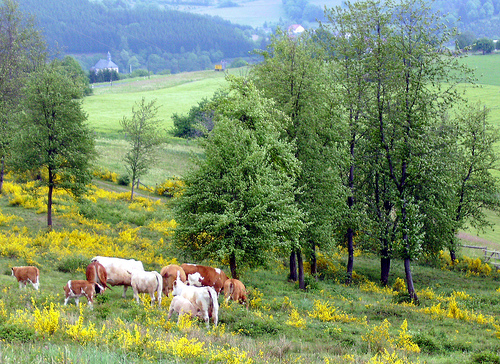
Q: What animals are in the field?
A: Cows.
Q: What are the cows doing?
A: Grazing.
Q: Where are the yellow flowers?
A: In the field.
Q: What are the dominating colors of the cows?
A: Brown and white.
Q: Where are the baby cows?
A: Right of the adults.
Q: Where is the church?
A: Foot of the mountain.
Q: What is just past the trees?
A: Grassy hills.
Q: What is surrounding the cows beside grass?
A: Flowers.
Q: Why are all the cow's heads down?
A: Eating.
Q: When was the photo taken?
A: During the daytime.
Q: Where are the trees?
A: Near animals.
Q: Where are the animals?
A: On the ground.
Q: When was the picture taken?
A: During the summer.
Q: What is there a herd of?
A: Cattle.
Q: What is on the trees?
A: Many branches.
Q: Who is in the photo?
A: No people.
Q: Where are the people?
A: None in photo.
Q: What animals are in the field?
A: Cows.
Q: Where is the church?
A: Across the field.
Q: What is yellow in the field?
A: Flowers.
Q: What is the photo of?
A: Fields.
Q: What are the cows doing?
A: Grazing.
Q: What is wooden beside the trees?
A: Fence.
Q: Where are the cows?
A: On the side of the hill.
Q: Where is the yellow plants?
A: On the side of the hill.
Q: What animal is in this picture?
A: Cows.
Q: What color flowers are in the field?
A: Yellow.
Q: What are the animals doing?
A: Grazing.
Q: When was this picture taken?
A: Daytime.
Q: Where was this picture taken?
A: Field.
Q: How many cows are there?
A: 10.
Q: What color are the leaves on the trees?
A: Green.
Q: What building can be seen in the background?
A: Church.